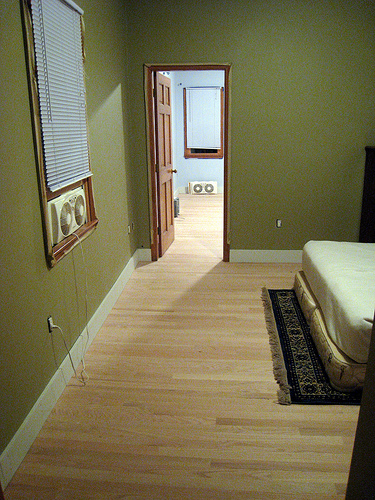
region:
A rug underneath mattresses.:
[257, 277, 370, 411]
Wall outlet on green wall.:
[43, 314, 55, 335]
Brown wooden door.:
[151, 68, 177, 254]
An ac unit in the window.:
[45, 182, 99, 250]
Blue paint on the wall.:
[173, 67, 232, 191]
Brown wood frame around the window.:
[179, 83, 226, 161]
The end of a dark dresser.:
[354, 136, 371, 238]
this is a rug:
[255, 279, 373, 413]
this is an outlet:
[45, 310, 60, 335]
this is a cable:
[32, 271, 102, 392]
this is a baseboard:
[1, 290, 116, 483]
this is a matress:
[337, 275, 363, 344]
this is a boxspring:
[286, 268, 372, 391]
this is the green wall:
[9, 294, 22, 311]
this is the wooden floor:
[156, 396, 226, 475]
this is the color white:
[47, 385, 55, 402]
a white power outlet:
[47, 317, 56, 330]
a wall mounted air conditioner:
[45, 182, 93, 245]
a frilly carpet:
[264, 281, 325, 412]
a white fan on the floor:
[188, 179, 220, 197]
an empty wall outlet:
[276, 218, 281, 227]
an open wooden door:
[151, 69, 175, 254]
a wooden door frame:
[145, 62, 230, 255]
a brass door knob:
[171, 167, 177, 174]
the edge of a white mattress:
[297, 234, 373, 371]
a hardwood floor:
[121, 259, 288, 489]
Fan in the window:
[46, 183, 90, 247]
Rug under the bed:
[263, 282, 363, 407]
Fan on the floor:
[185, 181, 217, 197]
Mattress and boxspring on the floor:
[292, 241, 373, 392]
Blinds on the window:
[29, 0, 94, 194]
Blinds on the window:
[183, 89, 223, 154]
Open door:
[152, 69, 178, 259]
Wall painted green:
[129, 0, 374, 248]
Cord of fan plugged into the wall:
[47, 232, 95, 382]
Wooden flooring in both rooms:
[4, 197, 358, 497]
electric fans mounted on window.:
[48, 184, 90, 246]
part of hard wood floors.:
[136, 323, 231, 499]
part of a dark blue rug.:
[253, 280, 295, 418]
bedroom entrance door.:
[149, 62, 231, 266]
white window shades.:
[31, 6, 100, 192]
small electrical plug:
[48, 318, 55, 332]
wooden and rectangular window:
[185, 88, 220, 157]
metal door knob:
[168, 166, 178, 176]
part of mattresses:
[294, 234, 367, 389]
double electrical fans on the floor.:
[186, 181, 216, 196]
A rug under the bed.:
[256, 271, 332, 409]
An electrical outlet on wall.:
[46, 310, 65, 334]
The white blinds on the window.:
[28, 5, 96, 186]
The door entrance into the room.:
[152, 64, 237, 272]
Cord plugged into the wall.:
[52, 320, 95, 377]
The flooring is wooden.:
[115, 287, 272, 480]